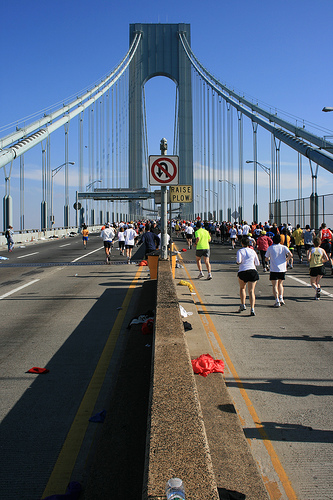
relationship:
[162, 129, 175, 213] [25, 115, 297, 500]
lightpost on bridge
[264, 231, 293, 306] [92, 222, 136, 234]
man running with hats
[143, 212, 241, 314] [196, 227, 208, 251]
man running with shirt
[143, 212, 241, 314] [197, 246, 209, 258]
man running with shorts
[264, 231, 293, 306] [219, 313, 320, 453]
man running on bridge